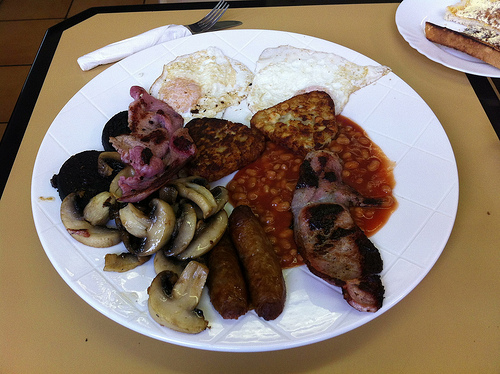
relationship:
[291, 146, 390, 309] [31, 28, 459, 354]
ham on plate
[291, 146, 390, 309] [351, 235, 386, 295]
ham has char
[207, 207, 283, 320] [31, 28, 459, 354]
sausages are on plate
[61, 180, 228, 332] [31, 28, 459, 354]
mushrooms are on plate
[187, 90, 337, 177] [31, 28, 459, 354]
hash browns are on plate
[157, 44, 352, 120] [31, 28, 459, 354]
eggs are on plate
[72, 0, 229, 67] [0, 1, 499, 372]
fork on table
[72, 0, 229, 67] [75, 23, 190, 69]
fork wrapped in napkin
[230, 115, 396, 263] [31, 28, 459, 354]
beans are on plate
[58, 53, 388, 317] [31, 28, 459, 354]
food on plate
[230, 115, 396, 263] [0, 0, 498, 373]
beans in photo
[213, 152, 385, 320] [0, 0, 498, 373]
meat in photo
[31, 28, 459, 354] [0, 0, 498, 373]
plate in photo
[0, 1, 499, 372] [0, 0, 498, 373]
table in photo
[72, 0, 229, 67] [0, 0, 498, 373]
fork in photo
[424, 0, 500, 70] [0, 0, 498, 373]
bread in photo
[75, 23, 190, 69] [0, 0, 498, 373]
serviette in photo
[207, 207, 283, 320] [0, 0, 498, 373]
sausages in photo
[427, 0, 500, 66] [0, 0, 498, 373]
bread in photo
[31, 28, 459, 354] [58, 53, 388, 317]
plate filled with food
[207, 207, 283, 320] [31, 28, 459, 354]
sausages on plate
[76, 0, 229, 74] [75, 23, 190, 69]
fork wrapped in napkin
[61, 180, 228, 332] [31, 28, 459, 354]
mushrooms on plate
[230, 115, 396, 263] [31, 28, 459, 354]
beans on plate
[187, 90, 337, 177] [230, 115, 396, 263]
hash browns with beans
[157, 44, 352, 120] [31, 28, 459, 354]
eggs on plate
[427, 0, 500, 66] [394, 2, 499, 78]
bread on plate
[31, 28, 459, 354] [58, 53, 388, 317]
plate of food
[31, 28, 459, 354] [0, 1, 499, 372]
plate on table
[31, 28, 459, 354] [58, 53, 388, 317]
plate with food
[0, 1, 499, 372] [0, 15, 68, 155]
table has edges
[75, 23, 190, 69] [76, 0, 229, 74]
napkin wrapped around fork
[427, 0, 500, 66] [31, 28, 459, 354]
bread on plate